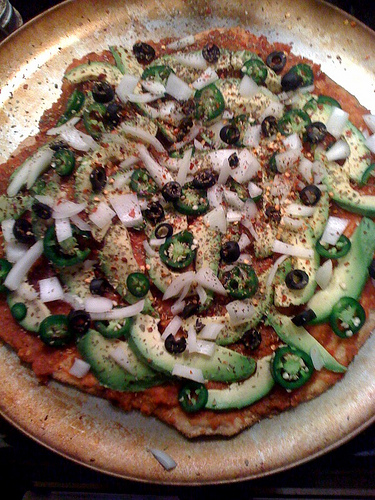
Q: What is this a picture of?
A: A pizza.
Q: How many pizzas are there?
A: 1.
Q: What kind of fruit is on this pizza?
A: Avocado.